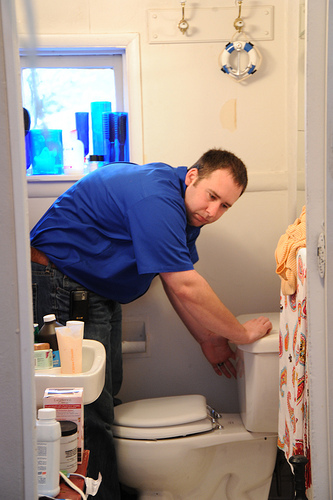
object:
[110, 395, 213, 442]
lid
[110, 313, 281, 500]
toilet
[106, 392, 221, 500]
seat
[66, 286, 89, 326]
phone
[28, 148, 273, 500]
man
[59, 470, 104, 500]
cord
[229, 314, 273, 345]
hand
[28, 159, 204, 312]
shirt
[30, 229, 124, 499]
jeans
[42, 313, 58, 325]
cap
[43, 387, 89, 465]
box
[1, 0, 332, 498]
bathroom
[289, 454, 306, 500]
handle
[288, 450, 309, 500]
plunger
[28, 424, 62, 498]
sink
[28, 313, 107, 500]
products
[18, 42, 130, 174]
items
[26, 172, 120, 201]
window sill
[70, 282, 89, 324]
case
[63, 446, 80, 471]
label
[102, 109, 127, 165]
hairbrushes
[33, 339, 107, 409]
pedestal sink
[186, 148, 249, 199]
hair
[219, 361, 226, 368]
wedding ring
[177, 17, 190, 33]
hook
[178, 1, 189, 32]
rack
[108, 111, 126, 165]
jar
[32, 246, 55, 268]
belt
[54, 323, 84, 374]
container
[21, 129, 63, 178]
life preserver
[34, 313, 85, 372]
bottle